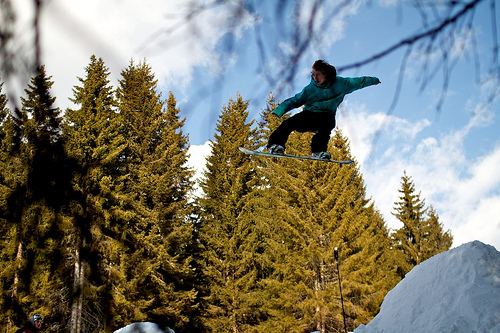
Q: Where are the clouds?
A: In sky.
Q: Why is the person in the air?
A: Doing a jump.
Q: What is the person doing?
A: Snowboarding.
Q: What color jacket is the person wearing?
A: Green.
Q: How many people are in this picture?
A: 1.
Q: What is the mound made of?
A: Snow.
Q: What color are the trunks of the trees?
A: Brown.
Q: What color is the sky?
A: Blue.